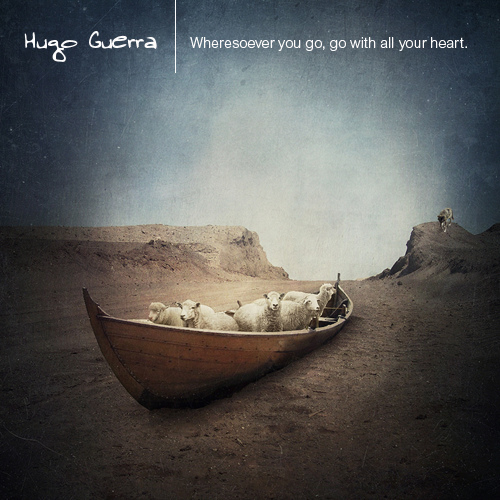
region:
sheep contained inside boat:
[30, 158, 475, 468]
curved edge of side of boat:
[80, 270, 355, 340]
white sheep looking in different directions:
[142, 280, 337, 331]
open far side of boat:
[77, 275, 342, 315]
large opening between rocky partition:
[227, 210, 424, 286]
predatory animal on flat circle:
[405, 201, 470, 258]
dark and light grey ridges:
[60, 211, 280, 276]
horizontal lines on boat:
[75, 285, 330, 417]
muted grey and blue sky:
[46, 76, 467, 277]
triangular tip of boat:
[76, 265, 107, 320]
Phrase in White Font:
[176, 21, 483, 76]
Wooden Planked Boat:
[67, 265, 370, 405]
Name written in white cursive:
[11, 22, 166, 66]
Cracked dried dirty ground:
[340, 296, 455, 491]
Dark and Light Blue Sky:
[5, 11, 496, 215]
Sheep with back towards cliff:
[390, 196, 474, 268]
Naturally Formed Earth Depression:
[185, 207, 438, 286]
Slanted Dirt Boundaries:
[25, 220, 270, 274]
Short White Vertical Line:
[160, 2, 191, 78]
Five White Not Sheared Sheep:
[126, 294, 384, 339]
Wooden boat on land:
[72, 299, 378, 396]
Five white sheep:
[144, 281, 339, 331]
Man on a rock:
[419, 204, 484, 254]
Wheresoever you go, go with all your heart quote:
[189, 27, 469, 58]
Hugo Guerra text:
[22, 26, 159, 58]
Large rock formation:
[56, 219, 300, 282]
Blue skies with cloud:
[46, 80, 479, 208]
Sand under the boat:
[277, 396, 452, 481]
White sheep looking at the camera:
[237, 289, 287, 327]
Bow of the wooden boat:
[81, 281, 178, 433]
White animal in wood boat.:
[186, 301, 240, 354]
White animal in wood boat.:
[133, 288, 178, 339]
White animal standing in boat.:
[231, 290, 283, 379]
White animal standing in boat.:
[283, 290, 335, 354]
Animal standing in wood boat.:
[311, 271, 341, 331]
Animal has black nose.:
[271, 298, 279, 310]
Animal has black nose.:
[179, 313, 191, 333]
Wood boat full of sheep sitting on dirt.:
[66, 261, 331, 457]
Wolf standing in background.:
[432, 184, 457, 266]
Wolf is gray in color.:
[422, 201, 478, 255]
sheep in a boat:
[63, 274, 387, 421]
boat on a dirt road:
[46, 280, 377, 482]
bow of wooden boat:
[67, 284, 263, 431]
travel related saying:
[183, 26, 483, 62]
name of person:
[10, 12, 169, 74]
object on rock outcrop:
[428, 196, 461, 243]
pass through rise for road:
[236, 218, 428, 288]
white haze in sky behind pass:
[163, 55, 425, 277]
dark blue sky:
[2, 55, 79, 222]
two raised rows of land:
[5, 217, 275, 288]